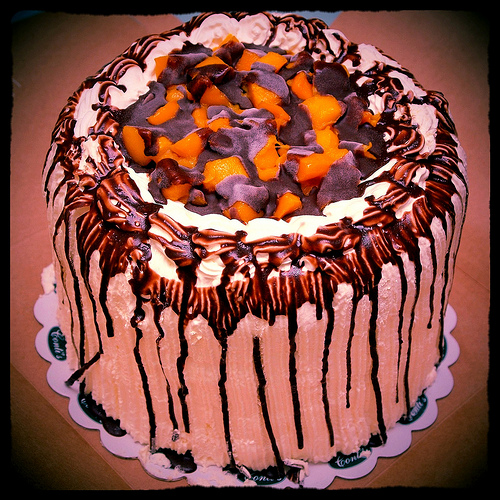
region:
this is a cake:
[314, 303, 389, 395]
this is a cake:
[136, 229, 229, 335]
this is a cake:
[78, 257, 183, 396]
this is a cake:
[294, 96, 381, 225]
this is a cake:
[271, 303, 377, 438]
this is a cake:
[93, 257, 196, 394]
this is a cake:
[63, 82, 146, 210]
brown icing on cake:
[144, 48, 351, 213]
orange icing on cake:
[148, 75, 318, 214]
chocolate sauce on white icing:
[84, 49, 395, 256]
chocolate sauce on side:
[45, 109, 441, 419]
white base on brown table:
[55, 109, 443, 459]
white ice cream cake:
[41, 55, 433, 459]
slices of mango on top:
[148, 90, 360, 208]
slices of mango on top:
[106, 72, 316, 215]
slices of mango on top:
[119, 80, 286, 222]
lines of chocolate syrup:
[159, 265, 283, 456]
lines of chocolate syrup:
[240, 218, 308, 349]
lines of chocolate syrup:
[197, 302, 359, 489]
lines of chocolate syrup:
[117, 292, 314, 486]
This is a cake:
[20, 49, 479, 479]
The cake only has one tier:
[22, 15, 454, 495]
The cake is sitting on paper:
[22, 283, 466, 495]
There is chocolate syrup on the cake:
[53, 200, 444, 441]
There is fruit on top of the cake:
[142, 52, 349, 206]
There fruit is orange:
[128, 32, 372, 224]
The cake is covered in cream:
[50, 39, 458, 448]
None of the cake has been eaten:
[24, 19, 472, 476]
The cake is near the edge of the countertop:
[44, 400, 431, 498]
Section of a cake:
[170, 200, 331, 497]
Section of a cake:
[318, 197, 465, 497]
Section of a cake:
[87, 154, 166, 449]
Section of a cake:
[157, 156, 346, 466]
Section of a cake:
[41, 99, 228, 496]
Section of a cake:
[232, 195, 431, 494]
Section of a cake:
[134, 103, 301, 493]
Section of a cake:
[271, 139, 456, 460]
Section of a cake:
[59, 118, 257, 498]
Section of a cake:
[191, 210, 381, 497]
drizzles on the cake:
[32, 17, 496, 481]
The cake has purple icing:
[132, 108, 397, 205]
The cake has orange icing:
[94, 107, 366, 367]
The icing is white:
[90, 230, 285, 483]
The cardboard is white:
[25, 277, 122, 446]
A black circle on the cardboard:
[29, 296, 76, 402]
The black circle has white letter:
[37, 321, 68, 364]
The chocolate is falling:
[275, 280, 325, 475]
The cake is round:
[17, 7, 453, 484]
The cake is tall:
[22, 5, 484, 483]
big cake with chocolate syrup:
[41, 14, 449, 478]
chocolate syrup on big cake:
[41, 14, 471, 450]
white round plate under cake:
[31, 257, 458, 487]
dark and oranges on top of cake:
[123, 38, 389, 225]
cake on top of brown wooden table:
[46, 9, 449, 471]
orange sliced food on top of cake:
[126, 25, 352, 220]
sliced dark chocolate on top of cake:
[115, 37, 387, 217]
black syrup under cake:
[44, 309, 446, 481]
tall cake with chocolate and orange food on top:
[51, 9, 466, 469]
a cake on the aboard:
[78, 46, 498, 486]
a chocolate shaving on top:
[309, 146, 346, 203]